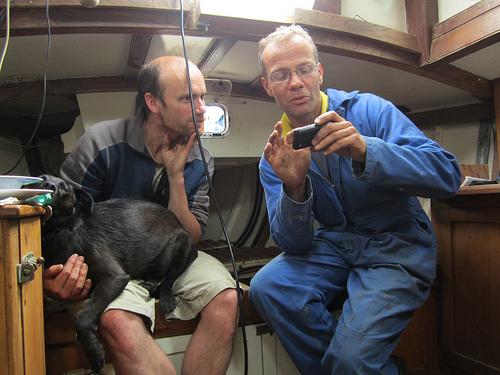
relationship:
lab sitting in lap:
[20, 176, 201, 374] [83, 222, 243, 324]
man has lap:
[44, 56, 238, 374] [83, 222, 243, 324]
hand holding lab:
[36, 252, 98, 305] [20, 176, 201, 374]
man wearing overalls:
[251, 25, 465, 374] [247, 89, 462, 374]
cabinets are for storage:
[104, 319, 304, 375] [102, 320, 295, 375]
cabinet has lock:
[3, 200, 57, 375] [16, 251, 47, 290]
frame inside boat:
[3, 0, 493, 138] [1, 3, 499, 375]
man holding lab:
[44, 56, 238, 374] [20, 176, 201, 374]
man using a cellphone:
[251, 25, 465, 374] [291, 122, 324, 148]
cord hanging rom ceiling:
[1, 1, 12, 80] [3, 6, 500, 131]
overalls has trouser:
[247, 89, 462, 374] [252, 213, 437, 374]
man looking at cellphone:
[44, 56, 238, 374] [291, 122, 324, 148]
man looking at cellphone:
[251, 25, 465, 374] [291, 122, 324, 148]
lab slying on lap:
[20, 176, 201, 374] [83, 222, 243, 324]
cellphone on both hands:
[291, 122, 324, 148] [263, 109, 366, 197]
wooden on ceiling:
[3, 0, 493, 138] [3, 6, 500, 131]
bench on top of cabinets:
[38, 269, 257, 336] [104, 319, 304, 375]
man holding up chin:
[44, 56, 238, 374] [40, 221, 89, 281]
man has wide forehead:
[251, 25, 465, 374] [255, 23, 322, 66]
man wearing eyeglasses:
[251, 25, 465, 374] [264, 60, 322, 90]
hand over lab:
[36, 252, 98, 305] [20, 176, 201, 374]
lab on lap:
[20, 176, 201, 374] [83, 222, 243, 324]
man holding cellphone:
[251, 25, 465, 374] [291, 122, 324, 148]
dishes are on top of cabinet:
[0, 169, 56, 205] [3, 200, 57, 375]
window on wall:
[199, 99, 232, 136] [46, 89, 410, 153]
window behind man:
[199, 99, 232, 136] [44, 56, 238, 374]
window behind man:
[199, 99, 232, 136] [251, 25, 465, 374]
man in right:
[251, 25, 465, 374] [240, 12, 468, 375]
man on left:
[44, 56, 238, 374] [57, 0, 232, 375]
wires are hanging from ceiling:
[0, 0, 249, 375] [3, 6, 500, 131]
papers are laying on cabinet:
[460, 170, 495, 190] [423, 183, 499, 374]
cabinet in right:
[423, 183, 499, 374] [240, 12, 468, 375]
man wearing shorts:
[44, 56, 238, 374] [98, 244, 236, 333]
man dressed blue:
[251, 25, 465, 374] [247, 89, 462, 374]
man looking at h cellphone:
[251, 25, 465, 374] [291, 122, 324, 148]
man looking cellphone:
[44, 56, 238, 374] [291, 122, 324, 148]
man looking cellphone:
[251, 25, 465, 374] [291, 122, 324, 148]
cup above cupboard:
[0, 175, 32, 207] [1, 171, 21, 203]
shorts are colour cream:
[98, 244, 236, 333] [102, 243, 229, 326]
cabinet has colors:
[3, 200, 57, 375] [0, 191, 52, 292]